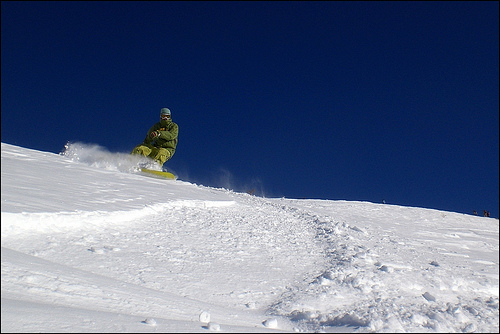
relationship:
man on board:
[137, 101, 194, 160] [144, 168, 185, 184]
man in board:
[137, 101, 194, 160] [144, 168, 185, 184]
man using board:
[137, 101, 194, 160] [144, 168, 185, 184]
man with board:
[137, 101, 194, 160] [144, 168, 185, 184]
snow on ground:
[366, 249, 416, 282] [45, 182, 198, 256]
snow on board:
[366, 249, 416, 282] [144, 168, 185, 184]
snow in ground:
[366, 249, 416, 282] [45, 182, 198, 256]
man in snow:
[137, 101, 194, 160] [366, 249, 416, 282]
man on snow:
[137, 101, 194, 160] [366, 249, 416, 282]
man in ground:
[137, 101, 194, 160] [45, 182, 198, 256]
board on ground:
[144, 168, 185, 184] [45, 182, 198, 256]